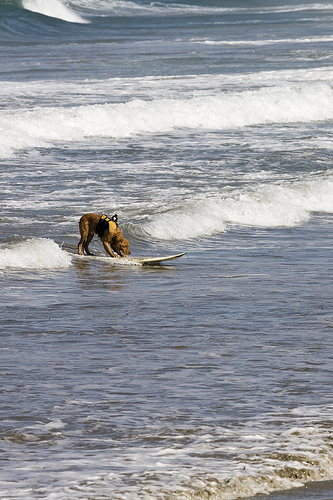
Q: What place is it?
A: It is a pond.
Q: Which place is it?
A: It is a pond.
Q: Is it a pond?
A: Yes, it is a pond.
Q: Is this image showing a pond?
A: Yes, it is showing a pond.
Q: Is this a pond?
A: Yes, it is a pond.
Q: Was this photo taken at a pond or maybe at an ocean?
A: It was taken at a pond.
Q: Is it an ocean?
A: No, it is a pond.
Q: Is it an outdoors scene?
A: Yes, it is outdoors.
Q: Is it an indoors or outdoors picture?
A: It is outdoors.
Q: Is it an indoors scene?
A: No, it is outdoors.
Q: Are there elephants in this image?
A: No, there are no elephants.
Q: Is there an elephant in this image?
A: No, there are no elephants.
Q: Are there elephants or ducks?
A: No, there are no elephants or ducks.